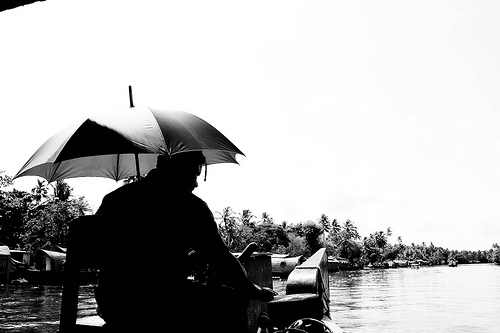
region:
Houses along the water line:
[325, 251, 456, 271]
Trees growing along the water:
[216, 200, 498, 265]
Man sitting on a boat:
[59, 146, 289, 328]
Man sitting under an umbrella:
[12, 87, 273, 332]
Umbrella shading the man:
[10, 103, 242, 183]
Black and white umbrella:
[17, 105, 247, 192]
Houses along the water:
[4, 240, 79, 298]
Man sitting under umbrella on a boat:
[10, 97, 345, 330]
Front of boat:
[245, 246, 342, 330]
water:
[329, 270, 486, 331]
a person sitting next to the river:
[20, 72, 375, 332]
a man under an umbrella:
[47, 117, 347, 331]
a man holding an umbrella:
[2, 78, 344, 331]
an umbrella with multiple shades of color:
[15, 67, 272, 212]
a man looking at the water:
[131, 122, 236, 214]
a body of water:
[316, 222, 492, 331]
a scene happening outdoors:
[7, 5, 499, 330]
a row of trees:
[0, 165, 497, 283]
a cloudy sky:
[1, 4, 498, 234]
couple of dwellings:
[333, 247, 492, 276]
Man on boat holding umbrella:
[11, 85, 267, 332]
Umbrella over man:
[10, 83, 252, 193]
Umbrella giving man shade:
[4, 83, 253, 198]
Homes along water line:
[325, 255, 440, 271]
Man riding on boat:
[90, 150, 335, 331]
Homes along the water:
[1, 244, 71, 288]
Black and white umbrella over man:
[10, 90, 243, 195]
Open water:
[334, 275, 487, 319]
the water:
[370, 231, 446, 327]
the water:
[364, 245, 408, 322]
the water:
[394, 223, 436, 320]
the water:
[342, 242, 386, 327]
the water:
[368, 262, 398, 314]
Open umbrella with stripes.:
[37, 98, 284, 203]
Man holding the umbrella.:
[33, 91, 289, 306]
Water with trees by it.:
[330, 210, 457, 313]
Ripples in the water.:
[334, 250, 489, 308]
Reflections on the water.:
[337, 243, 397, 329]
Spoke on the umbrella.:
[107, 70, 178, 125]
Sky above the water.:
[240, 81, 398, 323]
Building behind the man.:
[22, 220, 102, 281]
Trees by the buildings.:
[262, 211, 413, 278]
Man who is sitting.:
[36, 126, 312, 330]